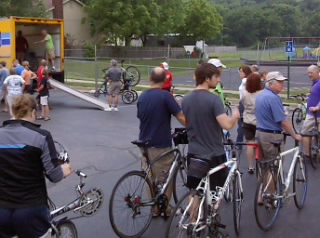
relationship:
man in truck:
[32, 29, 56, 72] [0, 15, 66, 91]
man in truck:
[16, 30, 30, 64] [0, 15, 66, 91]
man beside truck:
[0, 59, 10, 112] [0, 15, 66, 91]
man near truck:
[12, 58, 24, 76] [0, 15, 66, 91]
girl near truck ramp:
[21, 61, 37, 94] [48, 77, 108, 111]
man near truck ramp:
[37, 59, 47, 88] [48, 77, 108, 111]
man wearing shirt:
[135, 66, 185, 220] [137, 87, 182, 148]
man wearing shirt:
[3, 67, 26, 119] [4, 75, 25, 95]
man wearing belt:
[251, 71, 303, 206] [256, 125, 282, 135]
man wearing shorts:
[135, 66, 185, 220] [139, 142, 177, 189]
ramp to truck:
[48, 77, 108, 111] [0, 15, 66, 91]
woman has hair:
[1, 93, 72, 236] [10, 92, 36, 122]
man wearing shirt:
[32, 29, 56, 72] [42, 34, 54, 51]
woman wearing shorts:
[1, 93, 72, 236] [2, 205, 54, 237]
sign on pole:
[283, 39, 295, 54] [285, 54, 290, 101]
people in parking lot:
[134, 58, 320, 238] [0, 87, 319, 237]